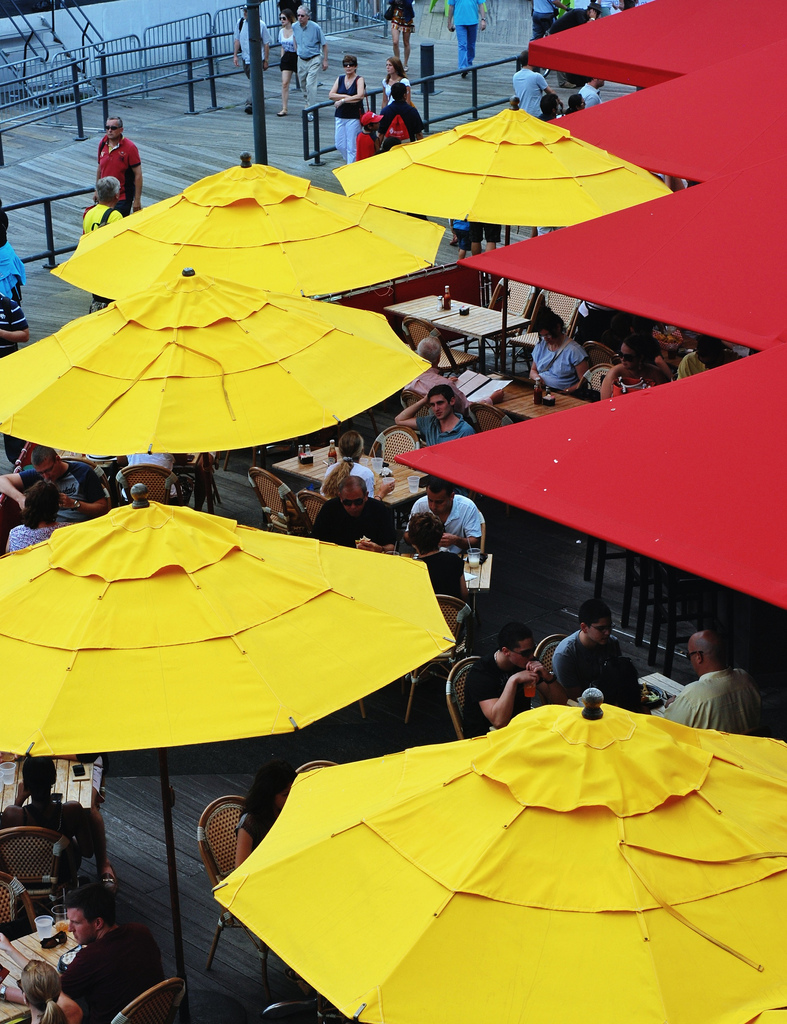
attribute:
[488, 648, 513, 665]
neck —  man's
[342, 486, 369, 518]
face —  man's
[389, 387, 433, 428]
arm —  man's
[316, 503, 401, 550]
shirt —  man's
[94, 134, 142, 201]
shirt —  red,  man's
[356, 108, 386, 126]
cap — red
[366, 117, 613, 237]
umbrella — yellow 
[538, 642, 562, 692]
chair — brown 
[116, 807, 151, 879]
floor — hardwood 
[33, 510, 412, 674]
umbrella — yellow  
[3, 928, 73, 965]
table — wooden , brown  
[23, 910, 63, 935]
cup — clear  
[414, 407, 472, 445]
shirt — blue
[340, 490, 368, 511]
sunglasses — black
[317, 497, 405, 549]
shirt — black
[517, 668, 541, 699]
cup — plastic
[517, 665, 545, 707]
cup — plastic